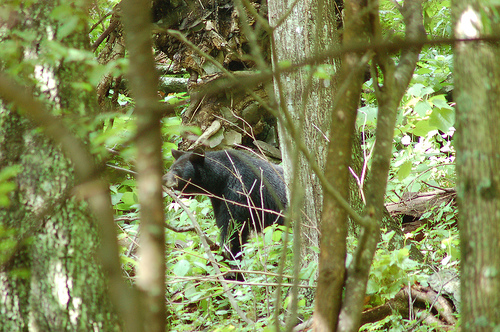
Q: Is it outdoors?
A: Yes, it is outdoors.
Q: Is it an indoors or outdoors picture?
A: It is outdoors.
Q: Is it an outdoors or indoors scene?
A: It is outdoors.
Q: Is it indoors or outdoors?
A: It is outdoors.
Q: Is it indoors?
A: No, it is outdoors.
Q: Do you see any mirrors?
A: No, there are no mirrors.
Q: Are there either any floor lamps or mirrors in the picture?
A: No, there are no mirrors or floor lamps.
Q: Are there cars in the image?
A: No, there are no cars.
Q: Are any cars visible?
A: No, there are no cars.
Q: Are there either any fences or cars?
A: No, there are no cars or fences.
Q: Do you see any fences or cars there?
A: No, there are no cars or fences.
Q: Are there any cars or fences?
A: No, there are no cars or fences.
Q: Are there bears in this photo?
A: Yes, there is a bear.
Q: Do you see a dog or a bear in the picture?
A: Yes, there is a bear.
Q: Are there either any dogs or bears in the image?
A: Yes, there is a bear.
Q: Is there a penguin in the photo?
A: No, there are no penguins.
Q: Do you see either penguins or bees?
A: No, there are no penguins or bees.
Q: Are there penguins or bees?
A: No, there are no penguins or bees.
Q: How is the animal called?
A: The animal is a bear.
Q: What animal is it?
A: The animal is a bear.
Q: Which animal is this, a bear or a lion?
A: This is a bear.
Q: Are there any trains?
A: No, there are no trains.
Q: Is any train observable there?
A: No, there are no trains.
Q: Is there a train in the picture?
A: No, there are no trains.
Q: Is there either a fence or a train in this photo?
A: No, there are no trains or fences.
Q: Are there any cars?
A: No, there are no cars.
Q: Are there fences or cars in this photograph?
A: No, there are no cars or fences.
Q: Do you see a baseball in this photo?
A: No, there are no baseballs.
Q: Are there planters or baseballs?
A: No, there are no baseballs or planters.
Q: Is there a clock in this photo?
A: No, there are no clocks.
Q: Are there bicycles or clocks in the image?
A: No, there are no clocks or bicycles.